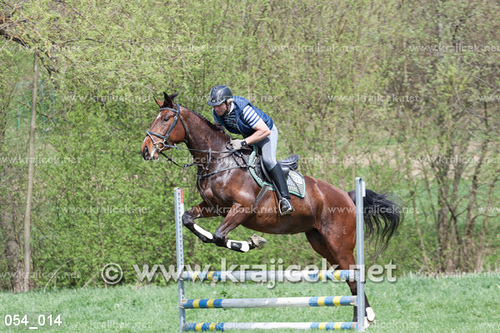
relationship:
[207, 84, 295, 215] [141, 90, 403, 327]
man on horse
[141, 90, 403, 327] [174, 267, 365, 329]
horse jumping hurdle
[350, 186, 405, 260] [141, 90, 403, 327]
tail of horse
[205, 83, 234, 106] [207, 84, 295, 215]
helmet on man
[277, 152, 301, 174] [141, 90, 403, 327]
saddle on horse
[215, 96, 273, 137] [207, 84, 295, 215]
vest on man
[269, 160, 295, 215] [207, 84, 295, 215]
boot on man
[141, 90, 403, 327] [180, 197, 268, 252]
horse has front legs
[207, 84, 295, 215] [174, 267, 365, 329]
man jumping hurdle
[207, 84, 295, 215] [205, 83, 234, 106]
man wearing a helmet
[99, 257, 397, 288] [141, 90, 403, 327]
watermark under horse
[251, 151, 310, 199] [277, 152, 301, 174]
pad under saddle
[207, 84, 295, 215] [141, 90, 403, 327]
man riding on horse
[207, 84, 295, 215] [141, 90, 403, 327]
man on top of horse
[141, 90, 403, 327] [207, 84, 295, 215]
horse jumping with man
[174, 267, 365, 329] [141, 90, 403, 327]
hurdle being jumped by horse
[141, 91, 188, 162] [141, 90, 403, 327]
head of horse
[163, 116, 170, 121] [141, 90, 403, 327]
eye of horse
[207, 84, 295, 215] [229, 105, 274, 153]
man has left arm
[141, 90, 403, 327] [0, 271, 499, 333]
horse in field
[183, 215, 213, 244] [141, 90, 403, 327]
guard on horse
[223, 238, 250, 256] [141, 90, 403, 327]
guard on horse